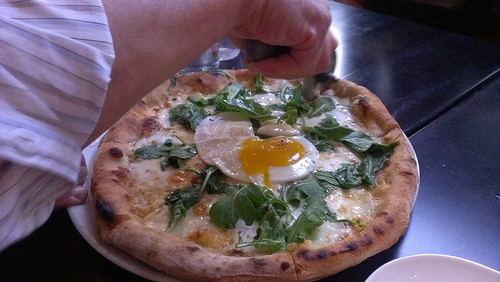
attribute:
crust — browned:
[284, 238, 370, 272]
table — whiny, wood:
[327, 1, 497, 280]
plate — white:
[66, 59, 420, 279]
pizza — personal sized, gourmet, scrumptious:
[91, 64, 420, 280]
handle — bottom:
[237, 37, 270, 62]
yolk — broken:
[190, 87, 330, 199]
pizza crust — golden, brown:
[85, 67, 422, 280]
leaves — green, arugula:
[156, 75, 396, 241]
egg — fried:
[198, 93, 320, 215]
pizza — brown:
[76, 40, 443, 277]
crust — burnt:
[89, 65, 419, 280]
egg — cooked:
[196, 108, 321, 187]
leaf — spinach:
[305, 114, 345, 145]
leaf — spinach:
[314, 115, 351, 149]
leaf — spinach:
[171, 99, 201, 132]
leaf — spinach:
[160, 189, 203, 223]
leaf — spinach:
[283, 173, 320, 199]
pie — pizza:
[88, 60, 423, 272]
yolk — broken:
[231, 128, 309, 170]